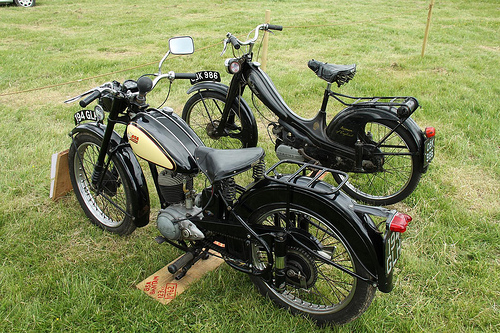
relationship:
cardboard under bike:
[136, 239, 229, 306] [64, 37, 412, 328]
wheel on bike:
[67, 132, 137, 237] [64, 37, 412, 328]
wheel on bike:
[229, 188, 377, 326] [64, 37, 412, 328]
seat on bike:
[193, 145, 265, 185] [64, 37, 412, 328]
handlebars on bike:
[79, 73, 197, 108] [64, 37, 412, 328]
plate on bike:
[380, 229, 400, 277] [64, 37, 412, 328]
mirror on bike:
[168, 36, 195, 56] [64, 37, 412, 328]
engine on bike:
[157, 167, 192, 204] [64, 37, 412, 328]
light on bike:
[385, 209, 412, 232] [64, 37, 412, 328]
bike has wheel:
[64, 37, 412, 328] [67, 132, 137, 237]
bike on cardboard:
[64, 37, 412, 328] [136, 239, 229, 306]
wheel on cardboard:
[67, 132, 137, 237] [136, 239, 229, 306]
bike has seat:
[64, 37, 412, 328] [193, 145, 265, 185]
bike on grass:
[64, 37, 412, 328] [1, 1, 498, 332]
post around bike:
[0, 1, 435, 98] [64, 37, 412, 328]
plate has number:
[380, 229, 400, 277] [385, 234, 393, 257]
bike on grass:
[64, 37, 412, 328] [17, 10, 462, 322]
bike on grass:
[64, 37, 412, 328] [35, 15, 447, 331]